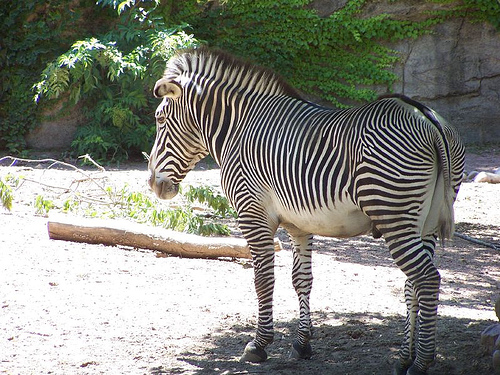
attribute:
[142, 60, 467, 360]
zebra — standing alone, single, standing still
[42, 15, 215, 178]
tree — small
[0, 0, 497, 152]
wall — rock, stone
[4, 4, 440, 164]
leaves — green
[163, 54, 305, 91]
mane — black, white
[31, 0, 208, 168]
tree — green, leafy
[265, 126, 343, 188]
stripes — black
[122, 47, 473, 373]
zebra — one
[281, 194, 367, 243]
belly — white